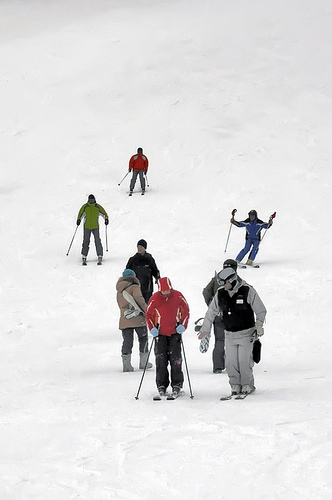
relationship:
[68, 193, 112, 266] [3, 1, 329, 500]
person skiing in snow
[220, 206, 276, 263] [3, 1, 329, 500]
person skiing in snow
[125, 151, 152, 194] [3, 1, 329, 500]
person skiing in snow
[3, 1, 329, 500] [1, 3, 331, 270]
snow on hill side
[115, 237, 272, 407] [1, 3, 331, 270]
people at bottom of hill side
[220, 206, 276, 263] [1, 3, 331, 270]
skier nearing bottom of hill side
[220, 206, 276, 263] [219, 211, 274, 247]
person raising poles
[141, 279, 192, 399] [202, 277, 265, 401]
skier talking to another skier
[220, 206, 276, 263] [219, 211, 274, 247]
person making motion with poles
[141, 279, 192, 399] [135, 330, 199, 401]
skier looking down with ski poles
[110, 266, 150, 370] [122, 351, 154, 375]
woman wearing boots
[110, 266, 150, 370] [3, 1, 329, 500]
woman walking on snow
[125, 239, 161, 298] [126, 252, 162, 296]
man in outfit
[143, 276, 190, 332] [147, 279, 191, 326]
sweater has stripes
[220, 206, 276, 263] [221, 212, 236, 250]
person holding ski pole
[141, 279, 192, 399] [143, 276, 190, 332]
skier wearing sweater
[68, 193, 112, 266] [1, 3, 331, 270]
person skiing down hill side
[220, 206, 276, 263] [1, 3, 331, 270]
person skiing down hill side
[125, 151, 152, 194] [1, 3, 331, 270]
person skiing down hill side